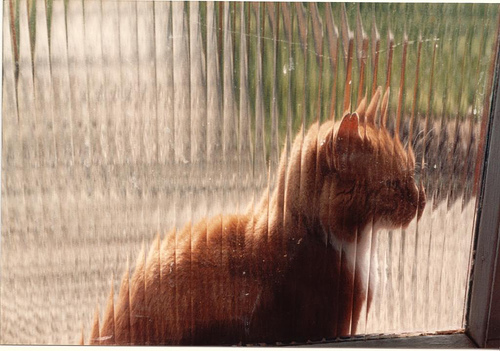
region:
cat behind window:
[97, 105, 428, 348]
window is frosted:
[38, 69, 466, 310]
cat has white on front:
[326, 236, 381, 296]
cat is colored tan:
[157, 97, 421, 349]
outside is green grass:
[271, 8, 481, 113]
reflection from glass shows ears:
[334, 81, 390, 131]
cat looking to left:
[306, 119, 446, 237]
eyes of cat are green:
[382, 170, 397, 210]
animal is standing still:
[116, 96, 406, 333]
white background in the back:
[0, 3, 261, 159]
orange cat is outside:
[253, 25, 460, 246]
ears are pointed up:
[271, 71, 444, 240]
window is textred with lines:
[208, 39, 346, 254]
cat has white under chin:
[331, 213, 398, 295]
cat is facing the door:
[364, 165, 433, 255]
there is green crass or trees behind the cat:
[239, 19, 488, 164]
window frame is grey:
[424, 120, 499, 332]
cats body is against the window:
[256, 236, 393, 327]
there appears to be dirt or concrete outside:
[48, 41, 468, 326]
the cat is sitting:
[121, 210, 364, 335]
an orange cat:
[74, 84, 426, 345]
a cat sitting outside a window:
[84, 94, 424, 338]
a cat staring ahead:
[78, 85, 428, 341]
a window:
[4, 1, 496, 338]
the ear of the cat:
[326, 110, 366, 167]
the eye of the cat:
[383, 170, 403, 190]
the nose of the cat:
[413, 192, 428, 209]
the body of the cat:
[72, 200, 305, 348]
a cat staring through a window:
[78, 94, 428, 334]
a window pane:
[7, 3, 481, 345]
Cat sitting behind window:
[5, 5, 493, 343]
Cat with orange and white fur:
[82, 84, 427, 344]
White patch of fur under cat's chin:
[322, 218, 392, 291]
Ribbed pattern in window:
[8, 5, 493, 345]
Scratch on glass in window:
[189, 16, 439, 62]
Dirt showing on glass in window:
[230, 233, 302, 325]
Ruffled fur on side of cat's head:
[331, 180, 355, 208]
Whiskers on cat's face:
[403, 121, 463, 187]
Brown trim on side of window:
[463, 8, 498, 348]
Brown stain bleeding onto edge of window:
[458, 13, 498, 333]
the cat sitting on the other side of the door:
[108, 95, 432, 336]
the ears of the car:
[335, 87, 391, 150]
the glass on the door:
[5, 3, 490, 340]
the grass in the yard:
[208, 6, 498, 129]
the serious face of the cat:
[365, 156, 425, 221]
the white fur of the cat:
[317, 220, 382, 283]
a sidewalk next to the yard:
[13, 8, 230, 290]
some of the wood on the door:
[478, 123, 498, 345]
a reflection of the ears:
[338, 27, 407, 107]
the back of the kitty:
[81, 212, 251, 329]